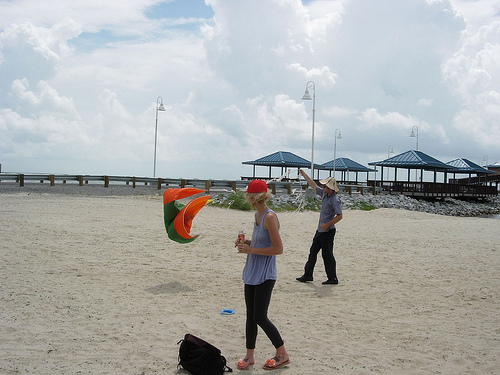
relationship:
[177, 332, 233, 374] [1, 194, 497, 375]
bag on sand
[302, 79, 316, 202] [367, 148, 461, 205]
light pole near pavilion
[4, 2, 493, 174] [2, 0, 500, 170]
sky has clouds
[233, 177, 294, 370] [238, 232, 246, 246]
person holding drink